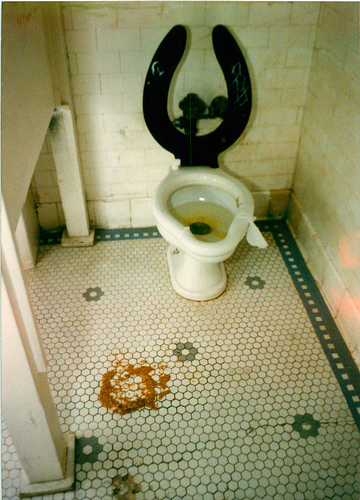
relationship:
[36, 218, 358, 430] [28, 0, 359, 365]
border around wall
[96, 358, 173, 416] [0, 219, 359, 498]
mud on floor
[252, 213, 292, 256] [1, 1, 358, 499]
paper on bathroom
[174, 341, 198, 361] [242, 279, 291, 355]
tile in flower pattern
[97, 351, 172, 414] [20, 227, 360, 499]
vomit on floor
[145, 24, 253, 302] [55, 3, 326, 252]
toilet on wall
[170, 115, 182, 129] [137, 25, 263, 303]
toilet handle on toilet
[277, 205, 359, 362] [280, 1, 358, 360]
base on wall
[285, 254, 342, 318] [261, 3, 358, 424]
tile on wall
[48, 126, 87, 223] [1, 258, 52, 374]
leg beside leg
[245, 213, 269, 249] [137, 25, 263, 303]
paper on toilet